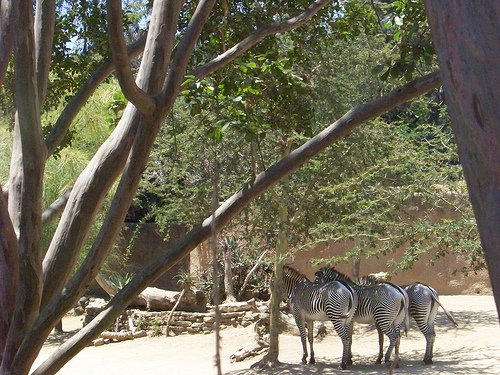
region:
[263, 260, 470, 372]
the butt ends of three zebra, all doing something different w/ their tails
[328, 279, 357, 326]
curves to the west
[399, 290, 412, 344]
points directly south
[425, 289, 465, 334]
goes off @ an easternly 45 degrees angle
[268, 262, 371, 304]
not a single head is visible, theyre all hidden behind something, but you do have a couple partials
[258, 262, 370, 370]
tall thin zebra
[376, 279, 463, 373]
short thinnish zebra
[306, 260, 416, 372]
long plumpish zebra, but nicely turned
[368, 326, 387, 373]
the leg of zebra number 3 [furthest] looking like it belongs to zebra no 2 [middle]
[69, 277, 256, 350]
a log atop a low wall of stones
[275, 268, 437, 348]
zebras standing in group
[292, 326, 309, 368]
leg of the zebra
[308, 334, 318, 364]
leg of the zebra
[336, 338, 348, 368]
leg of the zebra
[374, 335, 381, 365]
leg of the zebra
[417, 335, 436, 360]
leg of the zebra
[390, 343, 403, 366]
leg of the zebra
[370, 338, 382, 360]
leg of the zebra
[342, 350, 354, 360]
leg of the zebra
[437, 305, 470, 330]
tail of the zebra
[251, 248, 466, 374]
Three zebras standing side by side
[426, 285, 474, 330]
Zebra's white and black tail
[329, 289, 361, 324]
Zebra's black and white tail swishing to the side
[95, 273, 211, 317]
Large brown log on the ground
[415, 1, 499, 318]
Edge of a piece of wood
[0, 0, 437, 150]
Leaves of trees hanging down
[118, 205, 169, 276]
Long branch full of leaves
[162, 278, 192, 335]
Stick planted in the ground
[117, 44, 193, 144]
Intersection of tree branches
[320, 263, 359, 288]
Black and white zebra mane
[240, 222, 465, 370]
zebras side by side under shade of tree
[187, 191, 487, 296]
tan wall of enclosure behind zebras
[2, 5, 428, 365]
smooth tan branches fanning across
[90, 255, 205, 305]
curved trunk laying on its side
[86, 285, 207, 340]
sticks and logs in front of low rock partition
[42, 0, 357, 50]
blue sky through branches of leaves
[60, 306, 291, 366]
sun shining brightly on flat and tan ground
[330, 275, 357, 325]
tail curved to left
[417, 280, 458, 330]
straight tail pointing to right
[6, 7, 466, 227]
various trees growing over enclosure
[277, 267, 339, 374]
this is a zebra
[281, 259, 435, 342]
the zebras are three in number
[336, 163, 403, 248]
this is a tree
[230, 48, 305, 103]
the leaves are green in color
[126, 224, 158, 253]
this is a wall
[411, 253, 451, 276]
the wall is brown in color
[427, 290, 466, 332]
this is a tail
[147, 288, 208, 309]
this is a log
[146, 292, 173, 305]
the log is dry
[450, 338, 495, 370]
this is the ground